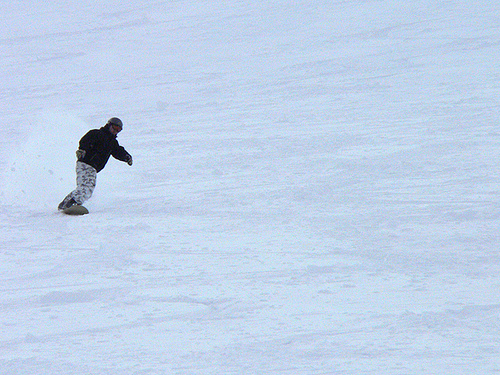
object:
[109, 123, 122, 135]
face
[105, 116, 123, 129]
cap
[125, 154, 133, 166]
gloves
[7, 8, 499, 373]
mountainside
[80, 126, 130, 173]
shirt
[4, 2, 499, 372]
hill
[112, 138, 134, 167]
extended arm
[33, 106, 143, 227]
snowboarder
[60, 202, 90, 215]
shoe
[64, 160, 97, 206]
legs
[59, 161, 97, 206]
pants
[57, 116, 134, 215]
man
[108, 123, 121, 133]
goggles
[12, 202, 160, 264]
tracks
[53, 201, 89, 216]
snowboard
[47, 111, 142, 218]
snowboarder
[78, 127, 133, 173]
coat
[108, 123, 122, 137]
mask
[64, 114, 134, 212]
snowboarder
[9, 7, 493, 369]
snow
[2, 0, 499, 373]
snowfall